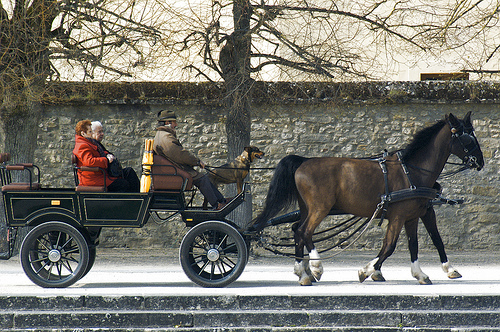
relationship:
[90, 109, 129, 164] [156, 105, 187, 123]
man wearing hat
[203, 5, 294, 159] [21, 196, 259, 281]
tree behind buggy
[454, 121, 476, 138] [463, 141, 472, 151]
blinder over eye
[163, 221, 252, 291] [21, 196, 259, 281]
wheels attached to buggy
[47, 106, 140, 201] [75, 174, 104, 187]
woman wearing red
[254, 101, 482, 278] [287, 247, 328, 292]
horse with hooves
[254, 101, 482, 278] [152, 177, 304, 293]
horse pulling chariot